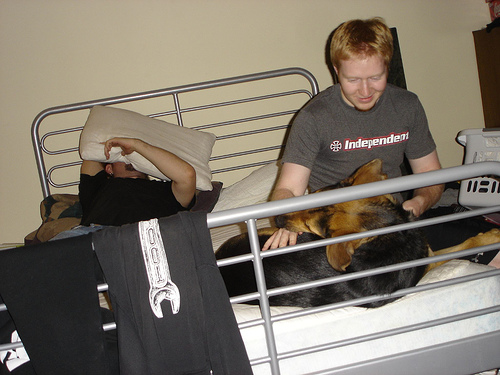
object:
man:
[262, 15, 446, 251]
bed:
[0, 66, 500, 375]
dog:
[213, 157, 499, 308]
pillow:
[79, 104, 216, 192]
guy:
[50, 136, 197, 241]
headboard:
[31, 67, 320, 198]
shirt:
[279, 82, 438, 206]